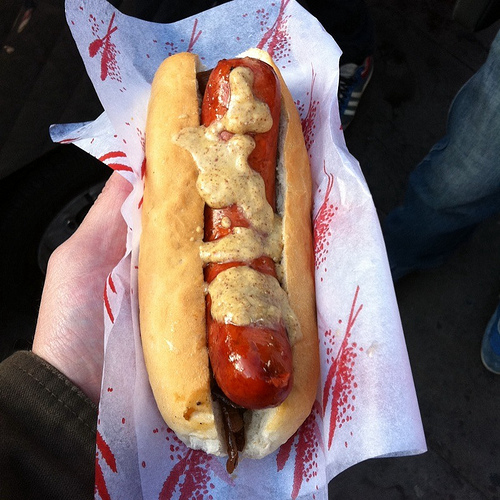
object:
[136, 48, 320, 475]
hotdog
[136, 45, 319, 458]
bun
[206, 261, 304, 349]
mustard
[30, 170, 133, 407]
hand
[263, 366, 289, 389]
tip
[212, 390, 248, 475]
onion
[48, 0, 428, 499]
paper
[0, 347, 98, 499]
sleeve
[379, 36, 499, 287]
jeans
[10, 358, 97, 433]
seam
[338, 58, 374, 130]
shoe